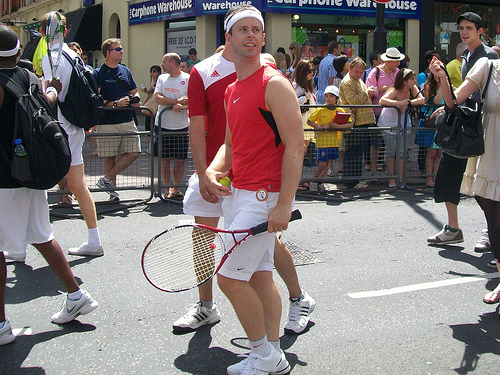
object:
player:
[204, 6, 307, 374]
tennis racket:
[142, 209, 303, 294]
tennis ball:
[218, 176, 232, 189]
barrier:
[297, 102, 471, 202]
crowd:
[260, 40, 465, 191]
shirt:
[222, 65, 297, 193]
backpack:
[0, 67, 73, 189]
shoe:
[239, 346, 290, 374]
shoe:
[224, 349, 286, 374]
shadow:
[169, 319, 321, 375]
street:
[0, 110, 499, 374]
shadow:
[448, 303, 499, 374]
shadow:
[0, 320, 96, 375]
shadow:
[4, 258, 83, 307]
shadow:
[427, 243, 500, 289]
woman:
[429, 55, 499, 305]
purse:
[433, 60, 493, 157]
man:
[363, 47, 416, 182]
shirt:
[364, 65, 405, 116]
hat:
[380, 46, 406, 63]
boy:
[307, 85, 354, 191]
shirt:
[307, 103, 353, 149]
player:
[1, 23, 100, 345]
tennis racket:
[47, 10, 67, 81]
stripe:
[346, 271, 500, 299]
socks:
[246, 335, 272, 359]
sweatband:
[222, 9, 264, 34]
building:
[98, 1, 418, 124]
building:
[0, 0, 101, 69]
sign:
[128, 2, 418, 25]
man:
[172, 5, 317, 333]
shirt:
[187, 51, 284, 181]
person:
[338, 57, 381, 190]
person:
[377, 69, 426, 188]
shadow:
[142, 195, 183, 218]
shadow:
[92, 198, 143, 222]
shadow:
[2, 255, 98, 307]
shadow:
[44, 191, 83, 224]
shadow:
[383, 186, 443, 231]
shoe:
[68, 241, 104, 258]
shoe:
[49, 292, 98, 323]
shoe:
[0, 321, 15, 348]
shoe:
[284, 292, 316, 333]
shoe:
[171, 304, 222, 330]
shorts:
[219, 186, 297, 282]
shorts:
[1, 188, 56, 261]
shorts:
[64, 127, 86, 166]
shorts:
[181, 173, 226, 218]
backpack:
[51, 47, 104, 129]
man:
[89, 37, 147, 205]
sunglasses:
[106, 47, 123, 52]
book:
[332, 112, 352, 129]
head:
[223, 6, 266, 59]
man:
[37, 11, 106, 257]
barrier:
[40, 102, 192, 218]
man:
[147, 52, 190, 201]